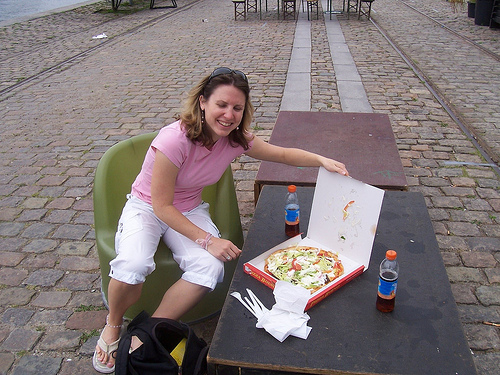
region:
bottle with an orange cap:
[373, 243, 413, 336]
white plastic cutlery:
[227, 284, 266, 326]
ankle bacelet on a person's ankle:
[96, 313, 124, 334]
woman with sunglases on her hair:
[182, 60, 262, 155]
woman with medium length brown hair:
[163, 59, 259, 159]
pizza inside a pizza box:
[256, 232, 368, 307]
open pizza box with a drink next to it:
[260, 166, 375, 306]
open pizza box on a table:
[269, 150, 379, 307]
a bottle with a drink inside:
[376, 243, 408, 335]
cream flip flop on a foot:
[78, 321, 120, 371]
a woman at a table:
[98, 43, 385, 318]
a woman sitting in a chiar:
[83, 25, 373, 372]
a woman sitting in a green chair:
[105, 61, 321, 346]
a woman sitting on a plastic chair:
[57, 23, 344, 365]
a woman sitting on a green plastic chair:
[72, 65, 279, 357]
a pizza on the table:
[250, 150, 432, 372]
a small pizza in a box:
[204, 139, 422, 362]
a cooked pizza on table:
[272, 156, 428, 331]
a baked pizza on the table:
[133, 145, 464, 373]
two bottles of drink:
[297, 161, 459, 373]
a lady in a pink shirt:
[98, 82, 243, 313]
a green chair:
[88, 110, 235, 314]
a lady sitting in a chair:
[130, 93, 245, 291]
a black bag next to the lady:
[107, 311, 172, 362]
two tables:
[235, 108, 446, 359]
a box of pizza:
[262, 170, 380, 293]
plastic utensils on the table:
[225, 290, 262, 310]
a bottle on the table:
[372, 243, 399, 303]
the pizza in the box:
[267, 240, 337, 286]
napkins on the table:
[267, 285, 312, 334]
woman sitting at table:
[108, 42, 215, 329]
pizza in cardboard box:
[270, 222, 345, 287]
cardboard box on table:
[235, 214, 399, 310]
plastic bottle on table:
[384, 240, 399, 296]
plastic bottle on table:
[278, 185, 301, 221]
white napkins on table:
[264, 277, 307, 337]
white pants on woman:
[122, 187, 222, 287]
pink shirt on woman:
[150, 122, 241, 213]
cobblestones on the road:
[21, 54, 153, 156]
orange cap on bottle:
[385, 248, 395, 260]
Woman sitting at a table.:
[87, 51, 347, 373]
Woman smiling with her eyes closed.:
[173, 60, 264, 155]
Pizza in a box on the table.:
[238, 159, 394, 315]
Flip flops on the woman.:
[88, 314, 127, 373]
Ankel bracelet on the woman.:
[103, 313, 123, 330]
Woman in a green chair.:
[86, 122, 248, 327]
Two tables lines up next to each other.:
[203, 104, 479, 373]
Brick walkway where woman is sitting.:
[1, 2, 498, 372]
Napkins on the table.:
[255, 278, 315, 345]